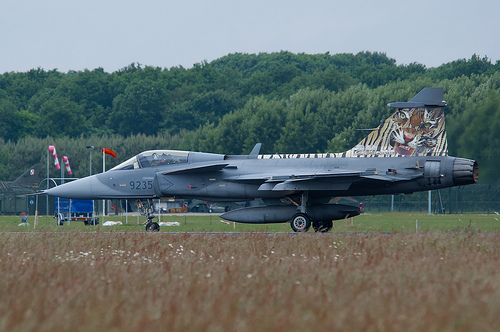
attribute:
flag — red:
[97, 140, 131, 173]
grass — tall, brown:
[1, 229, 496, 328]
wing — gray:
[227, 164, 380, 211]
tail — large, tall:
[350, 86, 480, 185]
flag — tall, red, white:
[38, 142, 63, 227]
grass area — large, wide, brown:
[1, 228, 499, 317]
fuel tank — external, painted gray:
[219, 201, 358, 223]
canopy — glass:
[136, 149, 188, 168]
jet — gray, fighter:
[34, 94, 479, 231]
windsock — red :
[102, 146, 120, 158]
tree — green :
[206, 54, 392, 103]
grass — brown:
[18, 231, 481, 324]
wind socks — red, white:
[43, 143, 70, 173]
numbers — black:
[127, 178, 159, 194]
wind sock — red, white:
[52, 143, 62, 170]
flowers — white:
[65, 245, 345, 265]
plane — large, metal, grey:
[42, 100, 476, 240]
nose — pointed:
[42, 171, 103, 202]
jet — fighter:
[43, 81, 482, 232]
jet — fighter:
[44, 101, 483, 218]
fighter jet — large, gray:
[45, 94, 484, 230]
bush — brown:
[14, 229, 479, 329]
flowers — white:
[55, 247, 336, 270]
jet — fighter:
[17, 63, 480, 233]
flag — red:
[98, 143, 120, 162]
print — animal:
[356, 105, 455, 156]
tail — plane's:
[353, 82, 450, 152]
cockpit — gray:
[106, 150, 187, 171]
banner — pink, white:
[61, 155, 74, 177]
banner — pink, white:
[45, 143, 61, 170]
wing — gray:
[225, 172, 416, 191]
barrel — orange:
[180, 203, 190, 214]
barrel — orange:
[173, 205, 178, 213]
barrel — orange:
[167, 204, 173, 211]